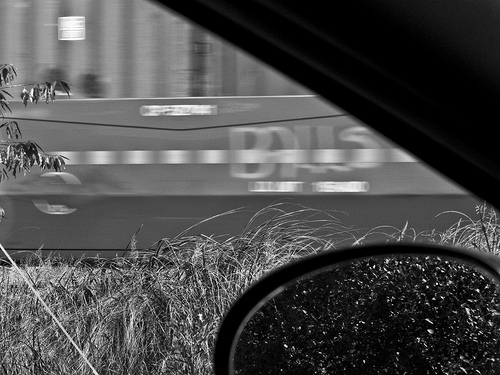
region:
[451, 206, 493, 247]
blades of vegetation by road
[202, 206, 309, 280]
blades of vegetation by road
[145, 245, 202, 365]
blades of vegetation by road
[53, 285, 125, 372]
blades of vegetation by road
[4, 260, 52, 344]
blades of vegetation by road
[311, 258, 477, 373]
image in rear view mirror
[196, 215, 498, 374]
rear view mirror of car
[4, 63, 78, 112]
small tree branch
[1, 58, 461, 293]
train passing by on tracks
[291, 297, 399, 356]
tree reflection in mirror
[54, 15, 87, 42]
Sign on the wall.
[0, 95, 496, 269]
Train on the tracks.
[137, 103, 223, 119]
White writing on the train.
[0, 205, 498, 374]
Long grass on the ground.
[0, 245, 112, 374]
Rope by the tree.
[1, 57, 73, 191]
Tree branches in front of the train.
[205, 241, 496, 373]
Circular black object in the forefront.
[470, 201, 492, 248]
Weed in the grass.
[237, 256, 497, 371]
Debris on the black object.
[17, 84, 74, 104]
Leaves on the branches.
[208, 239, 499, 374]
A rear view mirror.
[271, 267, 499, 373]
Many leaves in the rear view mirror.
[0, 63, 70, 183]
Leaves coming off a tree that are perfectly visible.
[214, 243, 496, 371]
black frame of a rear view mirror.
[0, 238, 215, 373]
High grass to the left of the mirror.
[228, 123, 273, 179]
The white letter B.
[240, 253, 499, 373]
Glass of the rear view mirror.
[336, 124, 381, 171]
The white letter S.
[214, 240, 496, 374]
A black and glass rear view mirror.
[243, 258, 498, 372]
All the leaves in the rear view mirror.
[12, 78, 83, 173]
leaves on tree branches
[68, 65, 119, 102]
shadows of leaves on walls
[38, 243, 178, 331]
tall grass growing up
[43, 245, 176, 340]
tall over grown weeds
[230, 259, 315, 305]
black outline of mirror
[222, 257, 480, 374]
side view mirror of car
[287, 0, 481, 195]
roof of car vehicle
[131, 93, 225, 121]
white writing on side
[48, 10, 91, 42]
white square sign on building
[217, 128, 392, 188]
white graffiti on building